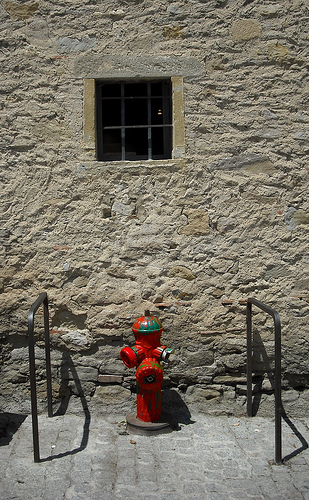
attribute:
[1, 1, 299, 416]
wall — rock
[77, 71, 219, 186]
window — inset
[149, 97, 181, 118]
light — inside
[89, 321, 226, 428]
hydrant — red, green, painted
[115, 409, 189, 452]
base — cement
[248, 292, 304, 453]
railing — black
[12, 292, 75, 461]
railing — black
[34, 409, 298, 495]
walkway — grey, stone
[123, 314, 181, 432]
hydrant — red, green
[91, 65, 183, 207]
windows — small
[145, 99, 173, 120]
light — hanging, indoor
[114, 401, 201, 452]
base — cement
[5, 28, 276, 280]
wall — stone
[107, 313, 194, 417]
hydrant — red, green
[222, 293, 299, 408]
railings — black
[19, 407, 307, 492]
sidewalk — stone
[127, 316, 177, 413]
hydrant — green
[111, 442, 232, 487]
ground — lined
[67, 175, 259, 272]
wall — rock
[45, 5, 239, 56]
wall — rock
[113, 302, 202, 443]
hydrant — red, green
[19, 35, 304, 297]
wall — stone, tan, gray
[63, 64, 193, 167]
window — square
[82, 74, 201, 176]
window — dark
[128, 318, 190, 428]
hydrant — green, red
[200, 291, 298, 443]
rails — black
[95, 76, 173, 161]
window — dark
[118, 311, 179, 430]
hydrant — red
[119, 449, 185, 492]
bricks — grey